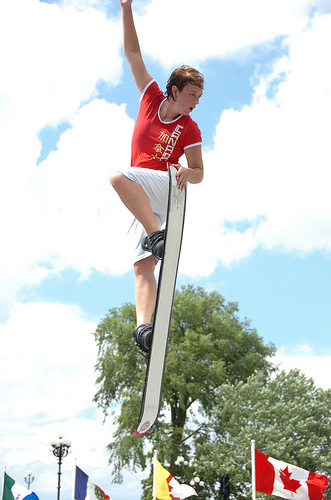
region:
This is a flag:
[237, 427, 323, 495]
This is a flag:
[143, 447, 196, 499]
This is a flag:
[69, 455, 110, 495]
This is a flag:
[48, 431, 73, 492]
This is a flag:
[19, 467, 45, 498]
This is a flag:
[1, 458, 17, 497]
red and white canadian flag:
[247, 435, 328, 498]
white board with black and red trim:
[121, 160, 191, 441]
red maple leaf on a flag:
[279, 464, 304, 497]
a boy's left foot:
[140, 226, 168, 260]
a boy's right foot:
[127, 319, 156, 351]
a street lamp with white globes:
[46, 430, 72, 498]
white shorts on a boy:
[115, 158, 173, 267]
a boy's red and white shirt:
[126, 74, 204, 178]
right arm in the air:
[117, 0, 160, 90]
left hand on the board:
[175, 161, 190, 189]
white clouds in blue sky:
[0, 0, 328, 497]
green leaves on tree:
[94, 284, 274, 480]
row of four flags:
[0, 439, 327, 498]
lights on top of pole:
[50, 436, 69, 498]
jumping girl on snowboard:
[109, 0, 204, 434]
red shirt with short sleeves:
[130, 77, 203, 168]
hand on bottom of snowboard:
[132, 162, 184, 434]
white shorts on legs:
[109, 167, 172, 265]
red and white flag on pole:
[250, 439, 325, 499]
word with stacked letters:
[162, 124, 183, 158]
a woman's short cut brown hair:
[161, 64, 206, 102]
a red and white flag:
[255, 448, 329, 498]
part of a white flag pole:
[249, 439, 259, 499]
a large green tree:
[93, 274, 276, 490]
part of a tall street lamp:
[51, 432, 77, 499]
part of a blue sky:
[235, 281, 330, 335]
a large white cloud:
[0, 297, 123, 424]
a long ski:
[135, 157, 191, 441]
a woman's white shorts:
[118, 162, 181, 267]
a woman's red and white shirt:
[131, 73, 203, 172]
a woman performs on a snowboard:
[119, 0, 209, 436]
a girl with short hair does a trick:
[118, 0, 206, 355]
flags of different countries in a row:
[1, 438, 330, 498]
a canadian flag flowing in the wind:
[248, 435, 330, 499]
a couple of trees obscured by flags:
[90, 281, 330, 491]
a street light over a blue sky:
[47, 433, 73, 499]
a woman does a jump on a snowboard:
[107, 0, 211, 446]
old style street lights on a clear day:
[20, 434, 72, 496]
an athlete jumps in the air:
[105, 1, 206, 366]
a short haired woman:
[155, 55, 207, 118]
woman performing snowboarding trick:
[105, 4, 200, 434]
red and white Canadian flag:
[252, 450, 329, 499]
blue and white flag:
[69, 465, 109, 499]